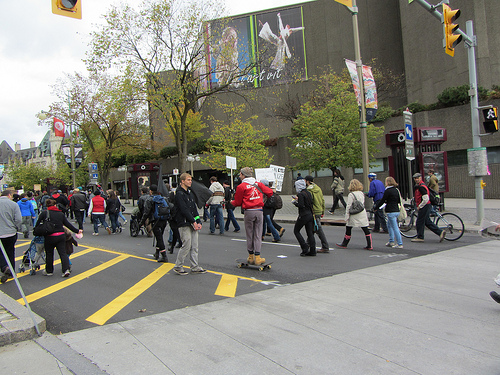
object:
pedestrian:
[373, 176, 408, 248]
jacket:
[0, 196, 23, 236]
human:
[0, 190, 30, 284]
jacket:
[139, 193, 174, 226]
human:
[139, 184, 175, 262]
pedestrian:
[291, 179, 316, 256]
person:
[336, 179, 373, 250]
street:
[0, 203, 499, 375]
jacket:
[231, 177, 273, 209]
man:
[230, 167, 273, 266]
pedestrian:
[304, 175, 329, 253]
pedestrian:
[260, 179, 281, 242]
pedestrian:
[223, 180, 240, 232]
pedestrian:
[105, 189, 122, 234]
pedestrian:
[70, 188, 87, 233]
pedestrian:
[17, 193, 36, 238]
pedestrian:
[427, 169, 441, 217]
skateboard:
[236, 258, 274, 271]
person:
[88, 191, 111, 236]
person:
[172, 173, 207, 276]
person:
[35, 199, 83, 277]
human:
[205, 176, 225, 235]